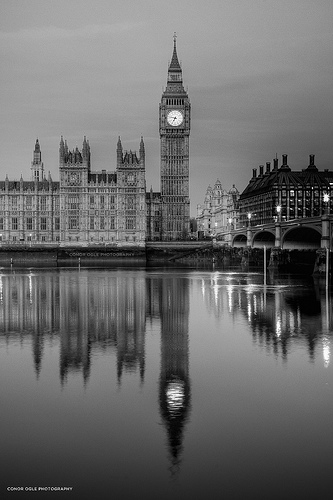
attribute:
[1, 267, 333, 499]
water — calm, dark, clear, pure, large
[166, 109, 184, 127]
clock — round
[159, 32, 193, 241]
clocktower — tall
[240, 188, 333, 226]
windows — cylindrical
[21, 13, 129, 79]
sky — hazy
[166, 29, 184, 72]
spire — high